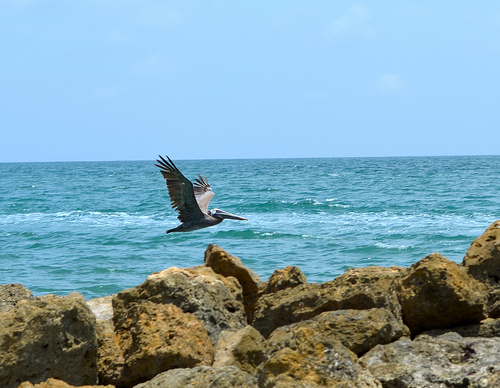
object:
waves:
[240, 194, 355, 218]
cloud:
[0, 0, 500, 162]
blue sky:
[0, 0, 499, 163]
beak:
[224, 211, 249, 220]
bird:
[151, 152, 248, 234]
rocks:
[257, 327, 386, 388]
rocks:
[0, 281, 104, 388]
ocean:
[0, 156, 500, 299]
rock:
[386, 251, 490, 333]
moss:
[414, 278, 464, 325]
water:
[0, 156, 500, 295]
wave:
[0, 205, 498, 234]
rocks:
[354, 329, 500, 388]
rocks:
[92, 301, 214, 383]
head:
[210, 207, 249, 221]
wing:
[151, 151, 199, 222]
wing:
[187, 172, 214, 215]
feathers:
[158, 153, 176, 171]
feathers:
[194, 173, 206, 185]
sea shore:
[0, 223, 500, 387]